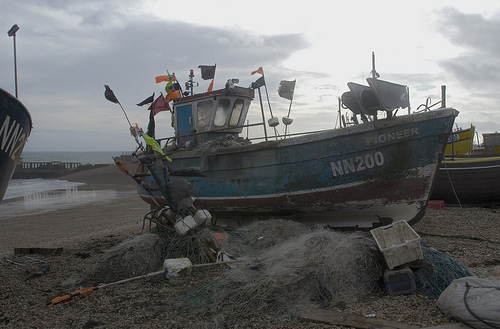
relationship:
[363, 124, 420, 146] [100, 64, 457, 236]
name on boat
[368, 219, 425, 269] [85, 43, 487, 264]
bin near front of boat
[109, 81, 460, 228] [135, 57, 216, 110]
boat with a lot of flags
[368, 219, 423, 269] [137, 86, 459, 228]
bin by boat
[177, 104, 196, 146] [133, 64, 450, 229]
door on boat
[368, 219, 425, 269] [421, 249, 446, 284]
bin under netting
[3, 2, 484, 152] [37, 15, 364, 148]
sky with clouds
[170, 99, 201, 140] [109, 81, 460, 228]
door on boat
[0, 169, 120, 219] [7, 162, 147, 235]
water coming to beach